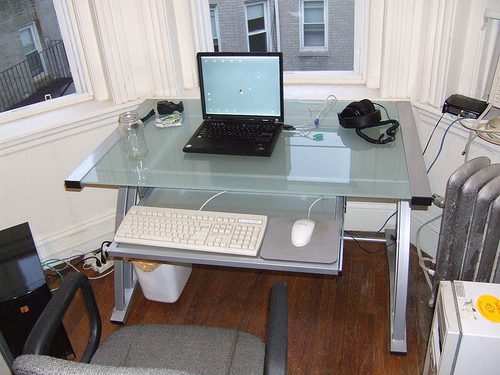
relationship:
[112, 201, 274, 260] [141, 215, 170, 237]
keyboard with keys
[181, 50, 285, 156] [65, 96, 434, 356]
laptop on desk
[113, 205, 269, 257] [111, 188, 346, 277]
keyboard on shelf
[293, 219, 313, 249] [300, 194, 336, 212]
mouse connected by mouse wire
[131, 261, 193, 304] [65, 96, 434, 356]
can under desk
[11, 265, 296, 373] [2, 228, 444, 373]
chair on a floor